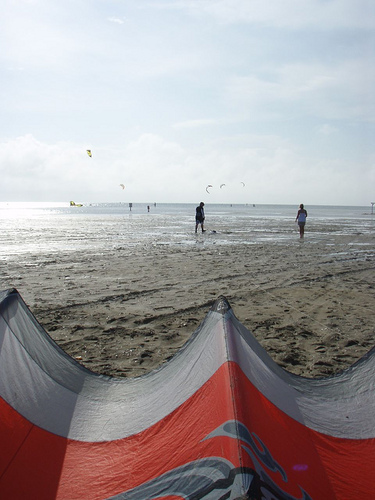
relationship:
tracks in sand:
[37, 238, 367, 332] [3, 219, 371, 383]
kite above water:
[82, 147, 96, 162] [0, 198, 372, 247]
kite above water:
[117, 179, 125, 191] [0, 198, 372, 247]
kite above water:
[201, 180, 213, 193] [0, 198, 372, 247]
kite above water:
[220, 180, 226, 189] [0, 198, 372, 247]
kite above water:
[238, 178, 247, 188] [0, 198, 372, 247]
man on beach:
[194, 201, 206, 234] [1, 215, 373, 378]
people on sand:
[294, 202, 308, 238] [238, 262, 345, 306]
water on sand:
[0, 203, 374, 251] [3, 219, 371, 383]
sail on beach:
[1, 291, 374, 498] [0, 232, 373, 497]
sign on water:
[125, 199, 137, 213] [41, 203, 374, 217]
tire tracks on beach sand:
[31, 251, 373, 353] [2, 205, 373, 392]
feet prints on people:
[243, 252, 362, 311] [294, 202, 308, 238]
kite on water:
[66, 197, 86, 209] [30, 194, 56, 228]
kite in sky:
[84, 149, 93, 159] [30, 21, 338, 206]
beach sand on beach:
[2, 205, 373, 383] [66, 247, 334, 310]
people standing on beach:
[294, 202, 308, 238] [106, 198, 369, 263]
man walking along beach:
[194, 201, 206, 234] [3, 207, 372, 352]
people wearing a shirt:
[294, 202, 308, 238] [294, 209, 317, 223]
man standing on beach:
[194, 201, 206, 234] [10, 221, 372, 241]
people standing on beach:
[294, 202, 308, 238] [10, 221, 372, 241]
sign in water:
[128, 202, 132, 211] [0, 203, 374, 251]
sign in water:
[145, 205, 149, 211] [0, 203, 374, 251]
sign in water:
[153, 201, 156, 206] [0, 203, 374, 251]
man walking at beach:
[194, 201, 206, 234] [8, 216, 373, 359]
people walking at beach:
[294, 202, 308, 238] [8, 216, 373, 359]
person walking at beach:
[147, 202, 150, 209] [8, 216, 373, 359]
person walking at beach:
[126, 200, 132, 210] [8, 216, 373, 359]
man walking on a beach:
[194, 201, 206, 234] [1, 215, 373, 378]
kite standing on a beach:
[240, 182, 245, 189] [1, 199, 371, 392]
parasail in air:
[116, 180, 124, 194] [32, 29, 338, 203]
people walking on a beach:
[65, 193, 317, 248] [1, 199, 371, 392]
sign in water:
[124, 201, 136, 209] [41, 203, 374, 217]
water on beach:
[41, 203, 374, 217] [3, 202, 374, 459]